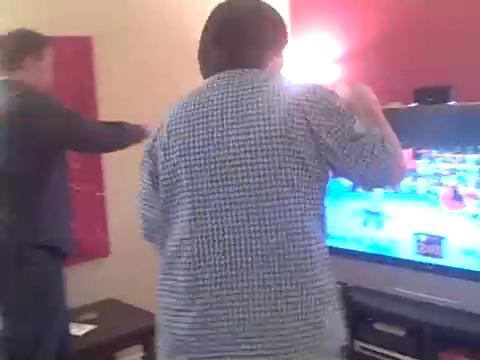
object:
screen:
[321, 127, 480, 280]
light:
[286, 38, 331, 80]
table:
[64, 298, 154, 360]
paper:
[68, 319, 96, 338]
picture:
[0, 0, 480, 360]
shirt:
[136, 69, 387, 360]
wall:
[262, 0, 480, 102]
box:
[359, 313, 421, 356]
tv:
[316, 102, 480, 337]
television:
[322, 100, 480, 341]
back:
[158, 87, 316, 312]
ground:
[122, 338, 146, 359]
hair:
[196, 0, 288, 78]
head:
[196, 0, 287, 80]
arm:
[52, 106, 143, 153]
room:
[0, 0, 480, 358]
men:
[0, 26, 146, 360]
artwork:
[49, 36, 109, 268]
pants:
[0, 251, 70, 360]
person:
[138, 0, 406, 360]